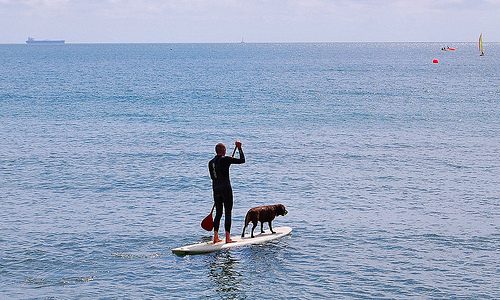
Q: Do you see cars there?
A: No, there are no cars.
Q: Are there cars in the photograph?
A: No, there are no cars.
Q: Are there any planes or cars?
A: No, there are no cars or planes.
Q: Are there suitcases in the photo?
A: No, there are no suitcases.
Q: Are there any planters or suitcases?
A: No, there are no suitcases or planters.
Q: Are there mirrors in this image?
A: No, there are no mirrors.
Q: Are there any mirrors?
A: No, there are no mirrors.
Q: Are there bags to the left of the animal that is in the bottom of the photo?
A: No, there is a paddle to the left of the dog.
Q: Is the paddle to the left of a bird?
A: No, the paddle is to the left of the dog.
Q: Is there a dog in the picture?
A: Yes, there is a dog.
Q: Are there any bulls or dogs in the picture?
A: Yes, there is a dog.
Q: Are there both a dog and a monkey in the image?
A: No, there is a dog but no monkeys.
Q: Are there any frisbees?
A: No, there are no frisbees.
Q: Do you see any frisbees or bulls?
A: No, there are no frisbees or bulls.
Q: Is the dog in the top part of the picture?
A: No, the dog is in the bottom of the image.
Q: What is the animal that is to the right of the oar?
A: The animal is a dog.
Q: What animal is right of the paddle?
A: The animal is a dog.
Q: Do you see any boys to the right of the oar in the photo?
A: No, there is a dog to the right of the oar.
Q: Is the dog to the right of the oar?
A: Yes, the dog is to the right of the oar.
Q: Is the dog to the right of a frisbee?
A: No, the dog is to the right of the oar.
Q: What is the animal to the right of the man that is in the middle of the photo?
A: The animal is a dog.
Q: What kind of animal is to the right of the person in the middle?
A: The animal is a dog.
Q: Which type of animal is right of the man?
A: The animal is a dog.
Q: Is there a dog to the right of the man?
A: Yes, there is a dog to the right of the man.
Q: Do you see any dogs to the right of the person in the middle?
A: Yes, there is a dog to the right of the man.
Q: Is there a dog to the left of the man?
A: No, the dog is to the right of the man.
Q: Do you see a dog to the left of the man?
A: No, the dog is to the right of the man.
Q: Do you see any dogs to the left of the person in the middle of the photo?
A: No, the dog is to the right of the man.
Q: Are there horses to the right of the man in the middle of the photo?
A: No, there is a dog to the right of the man.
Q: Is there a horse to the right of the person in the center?
A: No, there is a dog to the right of the man.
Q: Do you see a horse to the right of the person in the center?
A: No, there is a dog to the right of the man.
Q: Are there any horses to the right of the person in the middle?
A: No, there is a dog to the right of the man.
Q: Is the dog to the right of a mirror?
A: No, the dog is to the right of a man.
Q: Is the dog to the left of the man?
A: No, the dog is to the right of the man.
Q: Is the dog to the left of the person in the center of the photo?
A: No, the dog is to the right of the man.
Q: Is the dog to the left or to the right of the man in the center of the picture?
A: The dog is to the right of the man.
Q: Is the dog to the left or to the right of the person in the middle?
A: The dog is to the right of the man.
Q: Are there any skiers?
A: No, there are no skiers.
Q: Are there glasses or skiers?
A: No, there are no skiers or glasses.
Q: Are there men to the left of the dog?
A: Yes, there is a man to the left of the dog.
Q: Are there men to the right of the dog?
A: No, the man is to the left of the dog.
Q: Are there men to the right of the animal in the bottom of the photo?
A: No, the man is to the left of the dog.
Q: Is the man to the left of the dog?
A: Yes, the man is to the left of the dog.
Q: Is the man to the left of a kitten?
A: No, the man is to the left of the dog.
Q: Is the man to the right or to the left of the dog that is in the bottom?
A: The man is to the left of the dog.